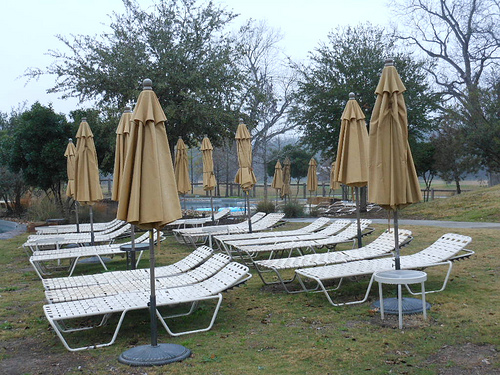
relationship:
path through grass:
[238, 218, 497, 233] [0, 182, 498, 371]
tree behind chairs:
[52, 4, 277, 155] [18, 204, 479, 354]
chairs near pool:
[297, 232, 486, 303] [184, 185, 304, 220]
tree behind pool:
[8, 0, 262, 155] [187, 191, 256, 218]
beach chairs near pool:
[35, 246, 247, 346] [187, 190, 288, 217]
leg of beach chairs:
[43, 317, 73, 349] [35, 261, 253, 352]